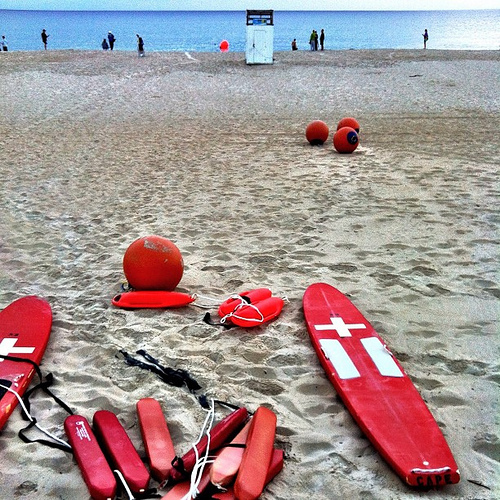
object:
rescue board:
[302, 281, 458, 490]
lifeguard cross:
[312, 314, 367, 343]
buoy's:
[121, 233, 185, 292]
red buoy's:
[329, 127, 358, 155]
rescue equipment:
[63, 413, 115, 498]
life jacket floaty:
[109, 291, 196, 312]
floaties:
[230, 401, 275, 497]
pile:
[293, 438, 340, 463]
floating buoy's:
[218, 296, 286, 331]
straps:
[120, 346, 213, 405]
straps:
[203, 397, 216, 500]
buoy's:
[1, 117, 500, 499]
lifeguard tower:
[243, 8, 272, 65]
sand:
[1, 51, 498, 499]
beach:
[1, 48, 500, 498]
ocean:
[1, 6, 499, 53]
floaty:
[62, 414, 113, 499]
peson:
[420, 26, 429, 51]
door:
[251, 28, 269, 64]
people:
[133, 33, 147, 57]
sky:
[1, 1, 498, 15]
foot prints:
[443, 357, 468, 379]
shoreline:
[0, 45, 498, 59]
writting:
[414, 471, 452, 489]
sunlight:
[429, 14, 500, 50]